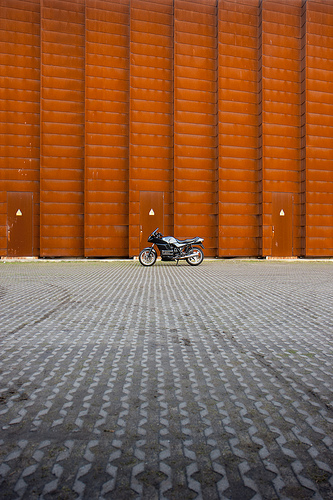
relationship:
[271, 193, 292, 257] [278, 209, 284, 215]
door with symbol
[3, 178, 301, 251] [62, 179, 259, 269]
doors in wall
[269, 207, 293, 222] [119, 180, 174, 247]
symbol on a door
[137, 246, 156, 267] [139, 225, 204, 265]
wheel on a bike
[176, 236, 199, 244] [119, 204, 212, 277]
seat on a bike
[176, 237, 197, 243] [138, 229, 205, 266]
seat of a motorcycle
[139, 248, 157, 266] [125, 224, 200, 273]
wheel of a cycle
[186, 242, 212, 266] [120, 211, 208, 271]
wheel of a cycle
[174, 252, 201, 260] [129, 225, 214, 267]
exhaust of a cycle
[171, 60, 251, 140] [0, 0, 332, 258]
walls of a building